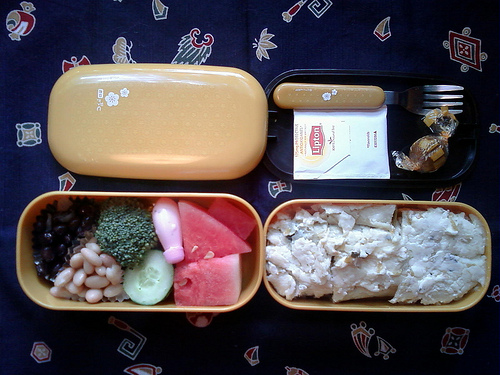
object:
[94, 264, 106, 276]
beans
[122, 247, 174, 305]
cucumber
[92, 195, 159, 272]
broccoli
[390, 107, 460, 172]
candy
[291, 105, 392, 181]
envelope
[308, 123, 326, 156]
label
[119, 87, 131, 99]
flowers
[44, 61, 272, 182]
cover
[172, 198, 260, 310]
watermelon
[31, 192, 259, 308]
meal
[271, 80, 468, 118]
fork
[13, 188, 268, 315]
container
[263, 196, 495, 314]
container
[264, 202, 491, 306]
food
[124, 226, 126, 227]
vegetables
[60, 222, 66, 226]
black beans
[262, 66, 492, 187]
plastic container